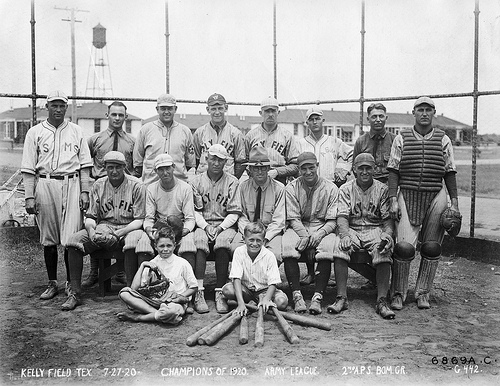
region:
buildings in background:
[0, 96, 474, 147]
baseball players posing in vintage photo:
[21, 85, 467, 327]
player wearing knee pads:
[390, 238, 442, 260]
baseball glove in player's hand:
[440, 200, 462, 244]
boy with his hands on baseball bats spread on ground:
[193, 223, 330, 352]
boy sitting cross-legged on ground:
[118, 222, 199, 331]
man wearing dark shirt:
[354, 128, 403, 178]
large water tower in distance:
[83, 15, 118, 111]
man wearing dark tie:
[98, 102, 134, 160]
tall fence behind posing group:
[0, 1, 496, 261]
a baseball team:
[23, 90, 475, 307]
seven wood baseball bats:
[188, 287, 338, 357]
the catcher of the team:
[394, 91, 467, 301]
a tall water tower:
[82, 17, 126, 95]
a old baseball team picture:
[16, 87, 476, 251]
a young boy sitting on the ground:
[126, 216, 208, 333]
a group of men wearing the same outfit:
[22, 96, 393, 258]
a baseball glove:
[441, 203, 468, 238]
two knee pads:
[389, 232, 449, 282]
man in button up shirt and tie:
[355, 93, 397, 158]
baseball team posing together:
[20, 92, 462, 314]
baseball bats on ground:
[185, 302, 332, 344]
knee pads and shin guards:
[392, 238, 440, 298]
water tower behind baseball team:
[80, 20, 117, 104]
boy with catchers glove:
[118, 225, 194, 326]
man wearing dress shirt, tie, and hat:
[231, 143, 282, 218]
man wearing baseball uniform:
[23, 90, 93, 310]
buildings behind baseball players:
[0, 95, 475, 157]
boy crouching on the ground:
[223, 220, 287, 305]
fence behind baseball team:
[0, 2, 498, 240]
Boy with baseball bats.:
[180, 223, 335, 354]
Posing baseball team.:
[16, 90, 456, 277]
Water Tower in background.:
[80, 21, 135, 92]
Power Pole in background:
[50, 0, 95, 105]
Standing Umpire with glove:
[395, 95, 450, 305]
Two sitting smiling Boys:
[125, 230, 285, 320]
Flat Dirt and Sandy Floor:
[0, 245, 495, 365]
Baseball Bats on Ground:
[176, 305, 331, 350]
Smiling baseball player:
[345, 151, 386, 321]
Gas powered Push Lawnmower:
[0, 165, 31, 238]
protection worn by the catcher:
[408, 135, 436, 225]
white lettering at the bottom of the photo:
[18, 363, 485, 381]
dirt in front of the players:
[346, 324, 486, 355]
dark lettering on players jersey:
[97, 197, 149, 217]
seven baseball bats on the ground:
[193, 303, 358, 350]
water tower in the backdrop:
[83, 19, 110, 81]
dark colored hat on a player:
[206, 91, 229, 111]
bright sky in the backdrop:
[186, 15, 270, 89]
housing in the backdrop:
[1, 102, 38, 136]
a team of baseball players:
[23, 98, 469, 319]